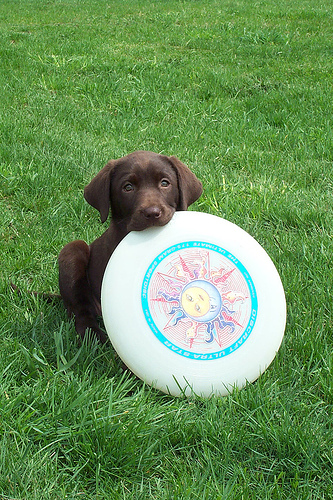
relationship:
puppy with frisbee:
[61, 147, 197, 337] [92, 209, 289, 394]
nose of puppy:
[145, 206, 160, 219] [9, 149, 202, 378]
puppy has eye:
[61, 147, 197, 337] [119, 180, 136, 193]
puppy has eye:
[61, 147, 197, 337] [158, 177, 173, 189]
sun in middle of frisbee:
[160, 248, 243, 354] [92, 209, 289, 394]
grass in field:
[0, 0, 331, 499] [2, 0, 322, 497]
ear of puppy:
[82, 160, 117, 222] [61, 147, 197, 337]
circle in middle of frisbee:
[140, 239, 255, 360] [92, 209, 289, 394]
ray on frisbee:
[175, 254, 194, 277] [92, 209, 289, 394]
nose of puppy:
[145, 206, 160, 219] [61, 147, 197, 337]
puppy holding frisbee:
[61, 147, 197, 337] [99, 211, 286, 410]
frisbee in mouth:
[92, 209, 289, 394] [127, 206, 178, 235]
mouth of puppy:
[127, 206, 178, 235] [61, 147, 197, 337]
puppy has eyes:
[61, 147, 197, 337] [119, 179, 177, 193]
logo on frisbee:
[148, 250, 251, 350] [92, 209, 289, 394]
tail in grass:
[6, 281, 62, 304] [0, 0, 331, 499]